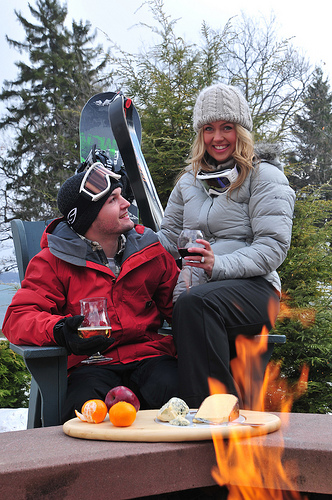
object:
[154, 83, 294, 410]
smiling woman